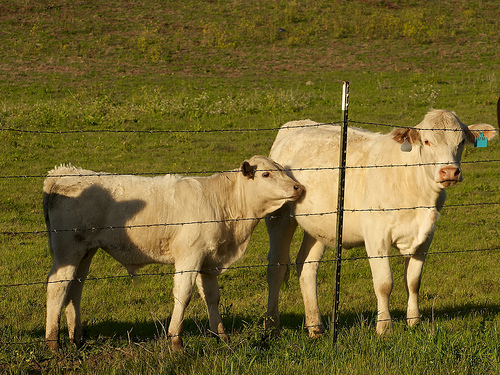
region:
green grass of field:
[3, 5, 494, 365]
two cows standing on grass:
[41, 108, 492, 350]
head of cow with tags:
[394, 109, 494, 190]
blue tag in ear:
[467, 124, 498, 149]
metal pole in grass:
[328, 81, 348, 350]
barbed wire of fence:
[0, 119, 497, 345]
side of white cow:
[41, 154, 303, 346]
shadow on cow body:
[40, 184, 152, 280]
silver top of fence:
[338, 79, 350, 116]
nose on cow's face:
[438, 165, 459, 183]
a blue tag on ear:
[463, 122, 496, 157]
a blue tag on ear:
[474, 114, 499, 154]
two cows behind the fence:
[18, 78, 460, 347]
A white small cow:
[41, 153, 306, 323]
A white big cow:
[282, 117, 452, 333]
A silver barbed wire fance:
[6, 138, 115, 344]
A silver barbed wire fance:
[137, 123, 281, 308]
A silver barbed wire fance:
[342, 116, 495, 320]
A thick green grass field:
[280, 331, 452, 373]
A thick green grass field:
[143, 336, 260, 371]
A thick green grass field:
[37, 81, 150, 130]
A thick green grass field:
[138, 87, 245, 127]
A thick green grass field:
[361, 59, 458, 114]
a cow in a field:
[41, 154, 305, 351]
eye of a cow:
[261, 169, 270, 179]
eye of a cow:
[422, 139, 429, 146]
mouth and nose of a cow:
[437, 166, 461, 186]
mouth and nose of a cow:
[291, 179, 303, 201]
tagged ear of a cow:
[468, 121, 495, 149]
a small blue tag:
[476, 133, 489, 151]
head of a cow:
[238, 153, 299, 212]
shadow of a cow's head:
[41, 185, 140, 270]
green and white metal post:
[328, 79, 350, 346]